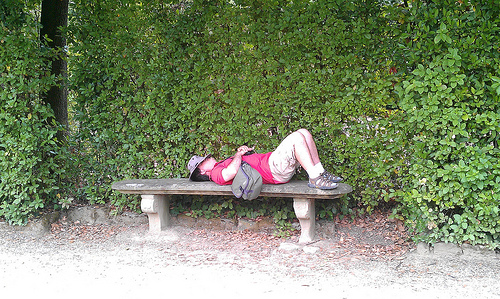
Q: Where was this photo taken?
A: In a park.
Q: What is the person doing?
A: Sleeping.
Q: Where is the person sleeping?
A: On a bench.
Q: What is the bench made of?
A: Concrete.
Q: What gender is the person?
A: Male.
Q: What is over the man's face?
A: A hat.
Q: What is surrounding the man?
A: Plants.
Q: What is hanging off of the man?
A: A bag.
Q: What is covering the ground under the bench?
A: Dried leaves.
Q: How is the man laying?
A: On his back.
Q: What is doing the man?
A: Sleeping.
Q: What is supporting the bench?
A: Two legs.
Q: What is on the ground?
A: Brown leaves.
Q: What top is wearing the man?
A: Tee shirt.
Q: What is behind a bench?
A: Trees.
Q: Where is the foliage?
A: Behind the bench.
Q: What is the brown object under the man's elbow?
A: Brown bag.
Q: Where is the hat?
A: Over the man's eyes.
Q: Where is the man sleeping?
A: Bench.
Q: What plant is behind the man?
A: Bushes.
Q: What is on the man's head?
A: Hat.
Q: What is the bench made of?
A: Concrete.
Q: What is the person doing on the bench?
A: Laying.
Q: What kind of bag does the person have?
A: Satchel.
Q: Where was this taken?
A: A garden.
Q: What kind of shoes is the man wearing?
A: Sandals.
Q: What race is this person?
A: White.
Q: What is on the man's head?
A: A hat.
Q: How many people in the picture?
A: One.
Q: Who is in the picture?
A: A man.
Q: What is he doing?
A: Sleeping.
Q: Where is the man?
A: Park bench.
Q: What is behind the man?
A: Hedge.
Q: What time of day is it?
A: Daytime.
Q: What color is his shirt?
A: Red.